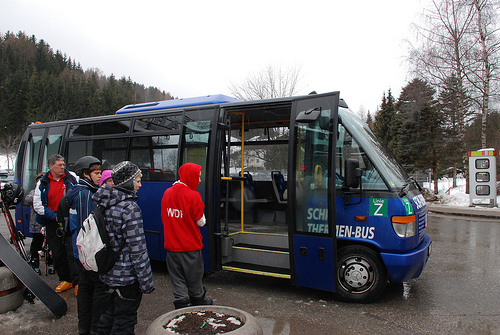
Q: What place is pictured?
A: It is a road.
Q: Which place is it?
A: It is a road.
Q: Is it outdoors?
A: Yes, it is outdoors.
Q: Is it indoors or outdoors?
A: It is outdoors.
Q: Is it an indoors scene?
A: No, it is outdoors.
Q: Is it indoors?
A: No, it is outdoors.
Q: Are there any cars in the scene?
A: No, there are no cars.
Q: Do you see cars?
A: No, there are no cars.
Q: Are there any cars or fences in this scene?
A: No, there are no cars or fences.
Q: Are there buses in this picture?
A: Yes, there is a bus.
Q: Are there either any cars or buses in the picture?
A: Yes, there is a bus.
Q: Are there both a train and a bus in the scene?
A: No, there is a bus but no trains.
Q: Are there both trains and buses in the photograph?
A: No, there is a bus but no trains.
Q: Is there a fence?
A: No, there are no fences.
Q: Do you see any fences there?
A: No, there are no fences.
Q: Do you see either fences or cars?
A: No, there are no fences or cars.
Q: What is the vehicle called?
A: The vehicle is a bus.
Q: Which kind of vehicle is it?
A: The vehicle is a bus.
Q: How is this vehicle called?
A: This is a bus.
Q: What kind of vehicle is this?
A: This is a bus.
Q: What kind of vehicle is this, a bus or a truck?
A: This is a bus.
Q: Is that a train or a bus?
A: That is a bus.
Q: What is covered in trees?
A: The hill is covered in trees.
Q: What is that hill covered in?
A: The hill is covered in trees.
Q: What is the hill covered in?
A: The hill is covered in trees.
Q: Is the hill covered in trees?
A: Yes, the hill is covered in trees.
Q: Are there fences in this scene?
A: No, there are no fences.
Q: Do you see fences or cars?
A: No, there are no fences or cars.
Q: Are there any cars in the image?
A: No, there are no cars.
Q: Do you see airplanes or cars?
A: No, there are no cars or airplanes.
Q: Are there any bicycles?
A: No, there are no bicycles.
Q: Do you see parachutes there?
A: No, there are no parachutes.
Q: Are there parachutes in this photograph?
A: No, there are no parachutes.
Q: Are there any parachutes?
A: No, there are no parachutes.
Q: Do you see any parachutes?
A: No, there are no parachutes.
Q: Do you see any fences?
A: No, there are no fences.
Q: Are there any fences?
A: No, there are no fences.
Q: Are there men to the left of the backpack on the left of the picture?
A: Yes, there is a man to the left of the backpack.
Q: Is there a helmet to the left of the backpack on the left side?
A: No, there is a man to the left of the backpack.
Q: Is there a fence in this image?
A: No, there are no fences.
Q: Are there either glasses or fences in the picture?
A: No, there are no fences or glasses.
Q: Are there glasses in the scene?
A: No, there are no glasses.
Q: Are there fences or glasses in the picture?
A: No, there are no glasses or fences.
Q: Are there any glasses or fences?
A: No, there are no glasses or fences.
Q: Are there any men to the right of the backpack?
A: Yes, there is a man to the right of the backpack.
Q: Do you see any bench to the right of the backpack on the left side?
A: No, there is a man to the right of the backpack.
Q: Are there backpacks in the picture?
A: Yes, there is a backpack.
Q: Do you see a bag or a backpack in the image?
A: Yes, there is a backpack.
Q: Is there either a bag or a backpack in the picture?
A: Yes, there is a backpack.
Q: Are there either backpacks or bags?
A: Yes, there is a backpack.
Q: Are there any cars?
A: No, there are no cars.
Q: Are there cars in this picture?
A: No, there are no cars.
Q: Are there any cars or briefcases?
A: No, there are no cars or briefcases.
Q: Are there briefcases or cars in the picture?
A: No, there are no cars or briefcases.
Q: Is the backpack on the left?
A: Yes, the backpack is on the left of the image.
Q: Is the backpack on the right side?
A: No, the backpack is on the left of the image.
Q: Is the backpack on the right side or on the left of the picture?
A: The backpack is on the left of the image.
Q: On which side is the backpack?
A: The backpack is on the left of the image.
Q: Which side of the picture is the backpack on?
A: The backpack is on the left of the image.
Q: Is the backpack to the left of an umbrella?
A: No, the backpack is to the left of a man.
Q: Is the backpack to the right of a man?
A: No, the backpack is to the left of a man.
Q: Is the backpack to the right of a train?
A: No, the backpack is to the right of a man.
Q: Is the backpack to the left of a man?
A: No, the backpack is to the right of a man.